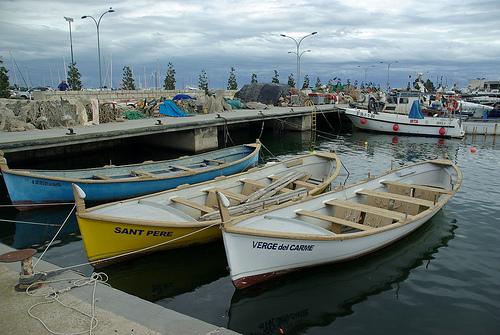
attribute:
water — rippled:
[112, 113, 483, 302]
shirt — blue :
[409, 100, 426, 121]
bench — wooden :
[297, 176, 443, 232]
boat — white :
[211, 154, 461, 282]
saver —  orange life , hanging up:
[432, 125, 450, 135]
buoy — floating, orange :
[464, 137, 484, 155]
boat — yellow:
[75, 147, 345, 267]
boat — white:
[177, 126, 472, 266]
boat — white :
[226, 157, 456, 282]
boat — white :
[214, 154, 464, 295]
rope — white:
[28, 270, 108, 330]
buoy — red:
[391, 121, 400, 130]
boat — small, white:
[340, 106, 465, 143]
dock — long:
[0, 100, 340, 170]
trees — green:
[1, 54, 385, 97]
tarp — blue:
[405, 97, 427, 121]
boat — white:
[338, 103, 468, 139]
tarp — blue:
[155, 98, 195, 117]